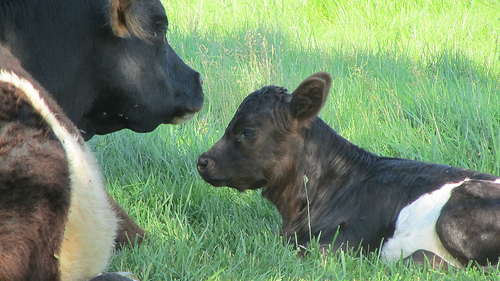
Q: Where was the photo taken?
A: It was taken at the field.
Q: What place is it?
A: It is a field.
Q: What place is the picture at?
A: It is at the field.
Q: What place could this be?
A: It is a field.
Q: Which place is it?
A: It is a field.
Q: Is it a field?
A: Yes, it is a field.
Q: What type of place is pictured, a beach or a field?
A: It is a field.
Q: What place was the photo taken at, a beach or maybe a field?
A: It was taken at a field.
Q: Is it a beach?
A: No, it is a field.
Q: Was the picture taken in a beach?
A: No, the picture was taken in a field.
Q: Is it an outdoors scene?
A: Yes, it is outdoors.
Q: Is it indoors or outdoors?
A: It is outdoors.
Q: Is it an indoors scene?
A: No, it is outdoors.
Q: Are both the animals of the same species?
A: Yes, all the animals are cows.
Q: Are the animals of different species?
A: No, all the animals are cows.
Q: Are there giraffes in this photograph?
A: No, there are no giraffes.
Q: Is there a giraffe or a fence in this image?
A: No, there are no giraffes or fences.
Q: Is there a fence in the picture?
A: No, there are no fences.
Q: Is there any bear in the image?
A: No, there are no bears.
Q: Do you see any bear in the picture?
A: No, there are no bears.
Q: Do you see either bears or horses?
A: No, there are no bears or horses.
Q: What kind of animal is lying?
A: The animal is a calf.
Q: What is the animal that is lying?
A: The animal is a calf.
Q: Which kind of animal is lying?
A: The animal is a calf.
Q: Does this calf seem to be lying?
A: Yes, the calf is lying.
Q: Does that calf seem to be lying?
A: Yes, the calf is lying.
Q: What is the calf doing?
A: The calf is lying.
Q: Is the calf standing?
A: No, the calf is lying.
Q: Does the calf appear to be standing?
A: No, the calf is lying.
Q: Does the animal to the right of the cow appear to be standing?
A: No, the calf is lying.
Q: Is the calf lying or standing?
A: The calf is lying.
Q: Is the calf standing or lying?
A: The calf is lying.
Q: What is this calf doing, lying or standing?
A: The calf is lying.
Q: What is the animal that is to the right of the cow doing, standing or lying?
A: The calf is lying.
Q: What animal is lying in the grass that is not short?
A: The calf is lying in the grass.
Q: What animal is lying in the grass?
A: The calf is lying in the grass.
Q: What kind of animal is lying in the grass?
A: The animal is a calf.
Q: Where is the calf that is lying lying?
A: The calf is lying in the grass.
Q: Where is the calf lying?
A: The calf is lying in the grass.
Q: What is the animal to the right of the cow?
A: The animal is a calf.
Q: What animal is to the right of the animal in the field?
A: The animal is a calf.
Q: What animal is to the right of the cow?
A: The animal is a calf.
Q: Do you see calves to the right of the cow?
A: Yes, there is a calf to the right of the cow.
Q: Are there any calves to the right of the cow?
A: Yes, there is a calf to the right of the cow.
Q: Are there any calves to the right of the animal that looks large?
A: Yes, there is a calf to the right of the cow.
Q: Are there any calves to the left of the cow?
A: No, the calf is to the right of the cow.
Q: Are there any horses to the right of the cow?
A: No, there is a calf to the right of the cow.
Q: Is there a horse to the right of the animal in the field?
A: No, there is a calf to the right of the cow.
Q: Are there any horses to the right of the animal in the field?
A: No, there is a calf to the right of the cow.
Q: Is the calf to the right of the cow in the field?
A: Yes, the calf is to the right of the cow.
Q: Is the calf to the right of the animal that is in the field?
A: Yes, the calf is to the right of the cow.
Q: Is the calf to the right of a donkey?
A: No, the calf is to the right of the cow.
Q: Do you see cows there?
A: Yes, there is a cow.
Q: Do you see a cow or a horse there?
A: Yes, there is a cow.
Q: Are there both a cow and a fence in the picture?
A: No, there is a cow but no fences.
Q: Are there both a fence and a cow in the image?
A: No, there is a cow but no fences.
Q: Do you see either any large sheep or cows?
A: Yes, there is a large cow.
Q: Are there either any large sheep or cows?
A: Yes, there is a large cow.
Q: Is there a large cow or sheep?
A: Yes, there is a large cow.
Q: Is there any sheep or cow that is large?
A: Yes, the cow is large.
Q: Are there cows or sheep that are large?
A: Yes, the cow is large.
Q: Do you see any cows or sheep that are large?
A: Yes, the cow is large.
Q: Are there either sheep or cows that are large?
A: Yes, the cow is large.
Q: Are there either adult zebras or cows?
A: Yes, there is an adult cow.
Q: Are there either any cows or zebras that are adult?
A: Yes, the cow is adult.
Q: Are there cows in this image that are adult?
A: Yes, there is an adult cow.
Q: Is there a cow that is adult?
A: Yes, there is a cow that is adult.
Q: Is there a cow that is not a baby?
A: Yes, there is a adult cow.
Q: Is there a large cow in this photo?
A: Yes, there is a large cow.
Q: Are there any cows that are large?
A: Yes, there is a cow that is large.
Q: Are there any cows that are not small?
A: Yes, there is a large cow.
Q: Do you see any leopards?
A: No, there are no leopards.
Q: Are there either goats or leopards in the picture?
A: No, there are no leopards or goats.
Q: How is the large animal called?
A: The animal is a cow.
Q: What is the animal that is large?
A: The animal is a cow.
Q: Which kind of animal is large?
A: The animal is a cow.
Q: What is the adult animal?
A: The animal is a cow.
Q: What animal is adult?
A: The animal is a cow.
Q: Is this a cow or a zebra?
A: This is a cow.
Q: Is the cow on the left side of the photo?
A: Yes, the cow is on the left of the image.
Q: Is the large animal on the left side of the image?
A: Yes, the cow is on the left of the image.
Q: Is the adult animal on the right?
A: No, the cow is on the left of the image.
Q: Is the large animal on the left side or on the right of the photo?
A: The cow is on the left of the image.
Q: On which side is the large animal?
A: The cow is on the left of the image.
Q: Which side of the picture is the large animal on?
A: The cow is on the left of the image.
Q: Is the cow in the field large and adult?
A: Yes, the cow is large and adult.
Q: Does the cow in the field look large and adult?
A: Yes, the cow is large and adult.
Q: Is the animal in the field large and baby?
A: No, the cow is large but adult.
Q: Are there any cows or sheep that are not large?
A: No, there is a cow but it is large.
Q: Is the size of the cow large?
A: Yes, the cow is large.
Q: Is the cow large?
A: Yes, the cow is large.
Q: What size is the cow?
A: The cow is large.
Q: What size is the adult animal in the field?
A: The cow is large.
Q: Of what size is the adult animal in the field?
A: The cow is large.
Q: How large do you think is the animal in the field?
A: The cow is large.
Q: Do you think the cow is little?
A: No, the cow is large.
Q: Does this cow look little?
A: No, the cow is large.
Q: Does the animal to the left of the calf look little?
A: No, the cow is large.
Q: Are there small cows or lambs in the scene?
A: No, there is a cow but it is large.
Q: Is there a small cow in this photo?
A: No, there is a cow but it is large.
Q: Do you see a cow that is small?
A: No, there is a cow but it is large.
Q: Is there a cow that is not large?
A: No, there is a cow but it is large.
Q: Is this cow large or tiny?
A: The cow is large.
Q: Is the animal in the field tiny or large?
A: The cow is large.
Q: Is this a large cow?
A: Yes, this is a large cow.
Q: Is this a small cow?
A: No, this is a large cow.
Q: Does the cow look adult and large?
A: Yes, the cow is adult and large.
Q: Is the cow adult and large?
A: Yes, the cow is adult and large.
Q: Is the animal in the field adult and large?
A: Yes, the cow is adult and large.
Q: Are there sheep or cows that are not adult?
A: No, there is a cow but it is adult.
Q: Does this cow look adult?
A: Yes, the cow is adult.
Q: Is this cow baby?
A: No, the cow is adult.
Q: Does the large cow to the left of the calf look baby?
A: No, the cow is adult.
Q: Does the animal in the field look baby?
A: No, the cow is adult.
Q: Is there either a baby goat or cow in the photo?
A: No, there is a cow but it is adult.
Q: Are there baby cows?
A: No, there is a cow but it is adult.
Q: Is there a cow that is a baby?
A: No, there is a cow but it is adult.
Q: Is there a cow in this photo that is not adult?
A: No, there is a cow but it is adult.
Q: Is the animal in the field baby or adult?
A: The cow is adult.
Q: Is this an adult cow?
A: Yes, this is an adult cow.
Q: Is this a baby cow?
A: No, this is an adult cow.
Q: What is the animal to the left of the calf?
A: The animal is a cow.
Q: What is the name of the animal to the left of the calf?
A: The animal is a cow.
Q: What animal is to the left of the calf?
A: The animal is a cow.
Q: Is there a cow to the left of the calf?
A: Yes, there is a cow to the left of the calf.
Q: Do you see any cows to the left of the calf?
A: Yes, there is a cow to the left of the calf.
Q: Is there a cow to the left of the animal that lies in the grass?
A: Yes, there is a cow to the left of the calf.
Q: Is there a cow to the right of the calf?
A: No, the cow is to the left of the calf.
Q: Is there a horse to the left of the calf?
A: No, there is a cow to the left of the calf.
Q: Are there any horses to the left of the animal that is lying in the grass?
A: No, there is a cow to the left of the calf.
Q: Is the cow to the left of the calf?
A: Yes, the cow is to the left of the calf.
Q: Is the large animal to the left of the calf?
A: Yes, the cow is to the left of the calf.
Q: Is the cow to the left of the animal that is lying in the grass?
A: Yes, the cow is to the left of the calf.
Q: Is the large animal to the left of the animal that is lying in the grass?
A: Yes, the cow is to the left of the calf.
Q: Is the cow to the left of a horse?
A: No, the cow is to the left of the calf.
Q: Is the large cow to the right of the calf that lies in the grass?
A: No, the cow is to the left of the calf.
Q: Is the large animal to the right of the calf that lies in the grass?
A: No, the cow is to the left of the calf.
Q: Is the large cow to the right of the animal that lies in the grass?
A: No, the cow is to the left of the calf.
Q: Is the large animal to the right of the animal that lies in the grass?
A: No, the cow is to the left of the calf.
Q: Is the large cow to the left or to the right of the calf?
A: The cow is to the left of the calf.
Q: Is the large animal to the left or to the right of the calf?
A: The cow is to the left of the calf.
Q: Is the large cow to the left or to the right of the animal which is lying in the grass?
A: The cow is to the left of the calf.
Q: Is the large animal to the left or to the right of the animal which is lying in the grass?
A: The cow is to the left of the calf.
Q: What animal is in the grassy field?
A: The cow is in the field.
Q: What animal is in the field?
A: The cow is in the field.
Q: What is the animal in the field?
A: The animal is a cow.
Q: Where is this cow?
A: The cow is in the field.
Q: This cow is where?
A: The cow is in the field.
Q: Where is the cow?
A: The cow is in the field.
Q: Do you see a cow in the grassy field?
A: Yes, there is a cow in the field.